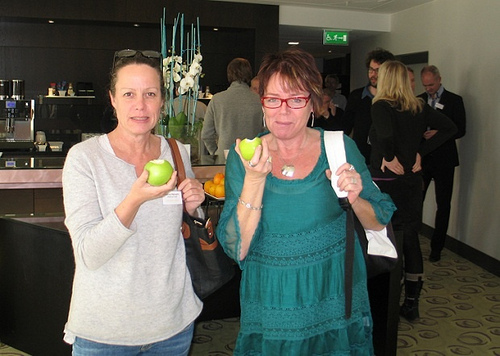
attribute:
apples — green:
[142, 144, 263, 173]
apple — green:
[238, 138, 264, 157]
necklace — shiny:
[277, 151, 308, 180]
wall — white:
[459, 22, 499, 63]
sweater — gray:
[218, 97, 260, 120]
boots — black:
[401, 280, 424, 322]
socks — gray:
[406, 274, 423, 280]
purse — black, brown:
[186, 214, 234, 300]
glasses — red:
[262, 90, 309, 112]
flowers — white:
[161, 50, 203, 96]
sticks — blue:
[155, 7, 203, 55]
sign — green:
[320, 29, 348, 45]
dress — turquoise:
[265, 199, 335, 338]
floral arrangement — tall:
[156, 8, 204, 130]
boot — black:
[406, 279, 419, 309]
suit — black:
[379, 108, 423, 160]